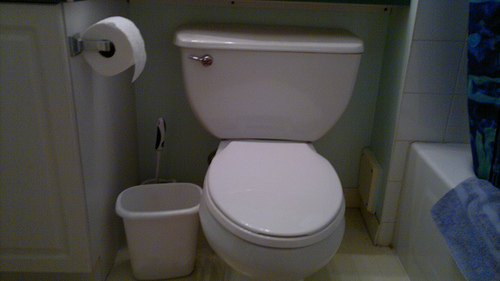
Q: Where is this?
A: This is at the bathroom.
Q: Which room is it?
A: It is a bathroom.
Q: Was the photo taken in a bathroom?
A: Yes, it was taken in a bathroom.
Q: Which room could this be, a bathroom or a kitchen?
A: It is a bathroom.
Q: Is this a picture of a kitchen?
A: No, the picture is showing a bathroom.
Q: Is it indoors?
A: Yes, it is indoors.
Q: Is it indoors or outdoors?
A: It is indoors.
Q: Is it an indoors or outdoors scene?
A: It is indoors.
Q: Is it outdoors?
A: No, it is indoors.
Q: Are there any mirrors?
A: No, there are no mirrors.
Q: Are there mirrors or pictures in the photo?
A: No, there are no mirrors or pictures.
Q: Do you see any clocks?
A: No, there are no clocks.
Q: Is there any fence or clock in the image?
A: No, there are no clocks or fences.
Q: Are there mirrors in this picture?
A: No, there are no mirrors.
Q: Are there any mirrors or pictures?
A: No, there are no mirrors or pictures.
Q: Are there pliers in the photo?
A: No, there are no pliers.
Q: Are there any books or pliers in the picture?
A: No, there are no pliers or books.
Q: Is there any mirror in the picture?
A: No, there are no mirrors.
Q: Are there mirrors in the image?
A: No, there are no mirrors.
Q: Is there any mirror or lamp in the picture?
A: No, there are no mirrors or lamps.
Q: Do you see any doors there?
A: Yes, there is a door.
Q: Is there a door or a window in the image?
A: Yes, there is a door.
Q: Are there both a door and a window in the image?
A: No, there is a door but no windows.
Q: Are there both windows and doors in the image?
A: No, there is a door but no windows.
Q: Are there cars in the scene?
A: No, there are no cars.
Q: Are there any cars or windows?
A: No, there are no cars or windows.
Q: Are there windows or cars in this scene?
A: No, there are no cars or windows.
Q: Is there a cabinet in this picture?
A: Yes, there is a cabinet.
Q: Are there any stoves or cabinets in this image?
A: Yes, there is a cabinet.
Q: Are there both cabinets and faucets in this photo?
A: No, there is a cabinet but no faucets.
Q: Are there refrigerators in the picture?
A: No, there are no refrigerators.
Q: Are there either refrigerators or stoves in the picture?
A: No, there are no refrigerators or stoves.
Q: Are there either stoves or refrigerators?
A: No, there are no refrigerators or stoves.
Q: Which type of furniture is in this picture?
A: The furniture is a cabinet.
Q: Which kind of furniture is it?
A: The piece of furniture is a cabinet.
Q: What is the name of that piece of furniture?
A: This is a cabinet.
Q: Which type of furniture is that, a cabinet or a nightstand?
A: This is a cabinet.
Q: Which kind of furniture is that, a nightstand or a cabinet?
A: This is a cabinet.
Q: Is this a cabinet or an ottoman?
A: This is a cabinet.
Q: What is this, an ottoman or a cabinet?
A: This is a cabinet.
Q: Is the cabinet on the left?
A: Yes, the cabinet is on the left of the image.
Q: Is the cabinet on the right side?
A: No, the cabinet is on the left of the image.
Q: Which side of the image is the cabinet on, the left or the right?
A: The cabinet is on the left of the image.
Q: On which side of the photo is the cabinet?
A: The cabinet is on the left of the image.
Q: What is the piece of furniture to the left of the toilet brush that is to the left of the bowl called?
A: The piece of furniture is a cabinet.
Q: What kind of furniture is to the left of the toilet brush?
A: The piece of furniture is a cabinet.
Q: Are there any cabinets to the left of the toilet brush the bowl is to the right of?
A: Yes, there is a cabinet to the left of the toilet brush.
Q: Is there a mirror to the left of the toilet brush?
A: No, there is a cabinet to the left of the toilet brush.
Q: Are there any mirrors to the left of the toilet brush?
A: No, there is a cabinet to the left of the toilet brush.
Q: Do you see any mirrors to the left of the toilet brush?
A: No, there is a cabinet to the left of the toilet brush.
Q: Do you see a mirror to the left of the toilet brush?
A: No, there is a cabinet to the left of the toilet brush.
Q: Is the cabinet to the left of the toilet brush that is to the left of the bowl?
A: Yes, the cabinet is to the left of the toilet brush.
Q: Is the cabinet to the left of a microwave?
A: No, the cabinet is to the left of the toilet brush.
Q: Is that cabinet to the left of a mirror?
A: No, the cabinet is to the left of a bowl.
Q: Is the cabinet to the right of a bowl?
A: No, the cabinet is to the left of a bowl.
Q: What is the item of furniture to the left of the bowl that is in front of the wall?
A: The piece of furniture is a cabinet.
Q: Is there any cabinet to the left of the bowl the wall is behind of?
A: Yes, there is a cabinet to the left of the bowl.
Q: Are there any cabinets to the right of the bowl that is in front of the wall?
A: No, the cabinet is to the left of the bowl.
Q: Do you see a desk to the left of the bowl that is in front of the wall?
A: No, there is a cabinet to the left of the bowl.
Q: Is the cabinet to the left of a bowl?
A: Yes, the cabinet is to the left of a bowl.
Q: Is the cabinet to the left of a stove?
A: No, the cabinet is to the left of a bowl.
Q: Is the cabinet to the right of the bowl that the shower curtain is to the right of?
A: No, the cabinet is to the left of the bowl.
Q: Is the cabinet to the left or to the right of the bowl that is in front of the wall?
A: The cabinet is to the left of the bowl.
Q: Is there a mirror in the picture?
A: No, there are no mirrors.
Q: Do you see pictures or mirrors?
A: No, there are no mirrors or pictures.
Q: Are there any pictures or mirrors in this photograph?
A: No, there are no mirrors or pictures.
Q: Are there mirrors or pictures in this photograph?
A: No, there are no mirrors or pictures.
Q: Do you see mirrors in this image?
A: No, there are no mirrors.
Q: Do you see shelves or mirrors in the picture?
A: No, there are no mirrors or shelves.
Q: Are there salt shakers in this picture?
A: No, there are no salt shakers.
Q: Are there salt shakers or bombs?
A: No, there are no salt shakers or bombs.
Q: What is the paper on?
A: The paper is on the wall.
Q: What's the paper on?
A: The paper is on the wall.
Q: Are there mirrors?
A: No, there are no mirrors.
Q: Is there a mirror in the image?
A: No, there are no mirrors.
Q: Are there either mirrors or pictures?
A: No, there are no mirrors or pictures.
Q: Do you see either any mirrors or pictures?
A: No, there are no mirrors or pictures.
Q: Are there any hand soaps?
A: No, there are no hand soaps.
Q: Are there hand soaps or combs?
A: No, there are no hand soaps or combs.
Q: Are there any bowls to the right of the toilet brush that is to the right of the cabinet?
A: Yes, there is a bowl to the right of the toilet brush.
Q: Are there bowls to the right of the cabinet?
A: Yes, there is a bowl to the right of the cabinet.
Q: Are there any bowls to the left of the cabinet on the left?
A: No, the bowl is to the right of the cabinet.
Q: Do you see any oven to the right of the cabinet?
A: No, there is a bowl to the right of the cabinet.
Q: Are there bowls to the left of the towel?
A: Yes, there is a bowl to the left of the towel.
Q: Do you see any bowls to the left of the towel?
A: Yes, there is a bowl to the left of the towel.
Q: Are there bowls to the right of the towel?
A: No, the bowl is to the left of the towel.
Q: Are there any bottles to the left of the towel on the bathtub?
A: No, there is a bowl to the left of the towel.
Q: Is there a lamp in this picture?
A: No, there are no lamps.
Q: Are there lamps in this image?
A: No, there are no lamps.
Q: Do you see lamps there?
A: No, there are no lamps.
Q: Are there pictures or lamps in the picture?
A: No, there are no lamps or pictures.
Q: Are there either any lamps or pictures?
A: No, there are no lamps or pictures.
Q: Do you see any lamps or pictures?
A: No, there are no lamps or pictures.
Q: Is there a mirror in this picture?
A: No, there are no mirrors.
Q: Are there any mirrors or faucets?
A: No, there are no mirrors or faucets.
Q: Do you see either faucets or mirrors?
A: No, there are no mirrors or faucets.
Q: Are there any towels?
A: Yes, there is a towel.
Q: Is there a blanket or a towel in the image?
A: Yes, there is a towel.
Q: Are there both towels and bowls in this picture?
A: Yes, there are both a towel and a bowl.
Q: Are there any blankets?
A: No, there are no blankets.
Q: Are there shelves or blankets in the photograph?
A: No, there are no blankets or shelves.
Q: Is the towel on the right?
A: Yes, the towel is on the right of the image.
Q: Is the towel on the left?
A: No, the towel is on the right of the image.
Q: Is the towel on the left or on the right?
A: The towel is on the right of the image.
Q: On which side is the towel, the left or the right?
A: The towel is on the right of the image.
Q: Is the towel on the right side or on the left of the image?
A: The towel is on the right of the image.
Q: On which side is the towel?
A: The towel is on the right of the image.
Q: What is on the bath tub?
A: The towel is on the bath tub.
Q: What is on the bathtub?
A: The towel is on the bath tub.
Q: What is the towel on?
A: The towel is on the bath tub.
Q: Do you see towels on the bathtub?
A: Yes, there is a towel on the bathtub.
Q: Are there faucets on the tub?
A: No, there is a towel on the tub.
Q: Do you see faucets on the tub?
A: No, there is a towel on the tub.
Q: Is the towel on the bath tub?
A: Yes, the towel is on the bath tub.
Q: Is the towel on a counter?
A: No, the towel is on the bath tub.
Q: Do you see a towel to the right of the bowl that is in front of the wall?
A: Yes, there is a towel to the right of the bowl.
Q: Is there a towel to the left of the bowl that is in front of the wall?
A: No, the towel is to the right of the bowl.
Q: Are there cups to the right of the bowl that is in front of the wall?
A: No, there is a towel to the right of the bowl.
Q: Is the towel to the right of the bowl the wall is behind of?
A: Yes, the towel is to the right of the bowl.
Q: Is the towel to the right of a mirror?
A: No, the towel is to the right of the bowl.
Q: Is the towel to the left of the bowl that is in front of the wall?
A: No, the towel is to the right of the bowl.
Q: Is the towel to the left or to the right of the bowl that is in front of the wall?
A: The towel is to the right of the bowl.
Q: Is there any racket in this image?
A: No, there are no rackets.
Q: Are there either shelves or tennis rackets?
A: No, there are no tennis rackets or shelves.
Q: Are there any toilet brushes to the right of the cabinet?
A: Yes, there is a toilet brush to the right of the cabinet.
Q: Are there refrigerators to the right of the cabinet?
A: No, there is a toilet brush to the right of the cabinet.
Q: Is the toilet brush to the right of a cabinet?
A: Yes, the toilet brush is to the right of a cabinet.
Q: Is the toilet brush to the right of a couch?
A: No, the toilet brush is to the right of a cabinet.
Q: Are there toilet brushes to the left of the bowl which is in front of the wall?
A: Yes, there is a toilet brush to the left of the bowl.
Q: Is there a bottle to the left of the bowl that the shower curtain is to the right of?
A: No, there is a toilet brush to the left of the bowl.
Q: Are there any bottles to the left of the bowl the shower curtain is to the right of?
A: No, there is a toilet brush to the left of the bowl.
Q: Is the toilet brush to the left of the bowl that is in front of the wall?
A: Yes, the toilet brush is to the left of the bowl.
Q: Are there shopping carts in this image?
A: No, there are no shopping carts.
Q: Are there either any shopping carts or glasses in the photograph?
A: No, there are no shopping carts or glasses.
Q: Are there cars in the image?
A: No, there are no cars.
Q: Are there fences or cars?
A: No, there are no cars or fences.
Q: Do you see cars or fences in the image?
A: No, there are no cars or fences.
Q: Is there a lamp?
A: No, there are no lamps.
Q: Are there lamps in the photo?
A: No, there are no lamps.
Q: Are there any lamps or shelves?
A: No, there are no lamps or shelves.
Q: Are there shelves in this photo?
A: No, there are no shelves.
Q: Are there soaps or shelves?
A: No, there are no shelves or soaps.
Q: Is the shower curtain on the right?
A: Yes, the shower curtain is on the right of the image.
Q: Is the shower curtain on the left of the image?
A: No, the shower curtain is on the right of the image.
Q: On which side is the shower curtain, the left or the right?
A: The shower curtain is on the right of the image.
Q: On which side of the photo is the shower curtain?
A: The shower curtain is on the right of the image.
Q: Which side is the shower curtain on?
A: The shower curtain is on the right of the image.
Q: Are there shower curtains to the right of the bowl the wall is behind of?
A: Yes, there is a shower curtain to the right of the bowl.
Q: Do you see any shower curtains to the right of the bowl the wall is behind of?
A: Yes, there is a shower curtain to the right of the bowl.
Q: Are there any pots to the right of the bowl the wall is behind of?
A: No, there is a shower curtain to the right of the bowl.